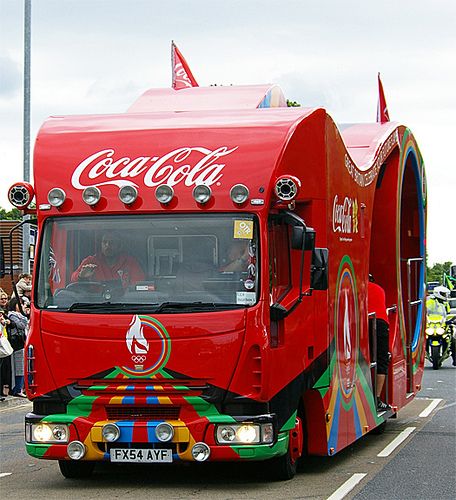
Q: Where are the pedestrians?
A: The sidewalk.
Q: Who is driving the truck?
A: The man.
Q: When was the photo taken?
A: Day time.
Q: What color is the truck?
A: Red.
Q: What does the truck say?
A: Coca cola.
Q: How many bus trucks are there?
A: One.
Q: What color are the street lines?
A: White.